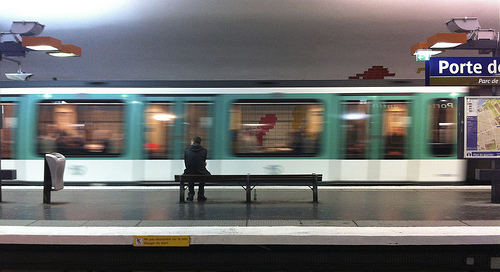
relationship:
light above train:
[406, 25, 468, 60] [32, 71, 472, 199]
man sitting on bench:
[185, 133, 208, 196] [176, 175, 325, 197]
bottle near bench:
[250, 186, 262, 204] [169, 164, 328, 209]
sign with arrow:
[415, 51, 435, 65] [405, 39, 450, 74]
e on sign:
[473, 63, 482, 74] [414, 50, 499, 95]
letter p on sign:
[435, 56, 450, 78] [455, 53, 495, 89]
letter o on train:
[478, 52, 497, 84] [34, 58, 496, 223]